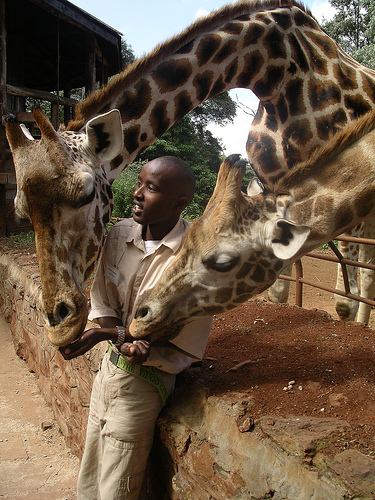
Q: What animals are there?
A: Giraffes.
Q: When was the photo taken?
A: Daytime.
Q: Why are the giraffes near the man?
A: He is feeding them.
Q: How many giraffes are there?
A: Two.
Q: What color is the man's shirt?
A: Beige.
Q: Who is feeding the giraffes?
A: The man.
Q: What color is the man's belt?
A: Green.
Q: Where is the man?
A: Between the giraffes.